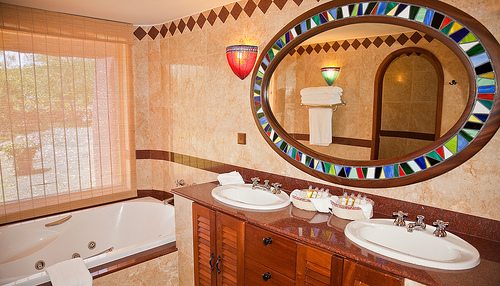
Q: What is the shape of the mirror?
A: Oval.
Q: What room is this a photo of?
A: Bathroom.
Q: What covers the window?
A: Blinds.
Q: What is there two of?
A: Sinks.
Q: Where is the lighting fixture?
A: On the wall.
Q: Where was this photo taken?
A: In the bathroom.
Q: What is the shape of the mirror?
A: Oval.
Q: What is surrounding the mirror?
A: Colorful tile.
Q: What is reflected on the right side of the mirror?
A: Doorway.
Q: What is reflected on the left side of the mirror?
A: Towels.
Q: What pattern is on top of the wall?
A: Diamonds.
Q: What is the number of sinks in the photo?
A: Two.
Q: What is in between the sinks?
A: Baskets.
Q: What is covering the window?
A: Blinds.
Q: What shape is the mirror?
A: Oval shaped.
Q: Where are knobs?
A: On drawers.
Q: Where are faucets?
A: Over the sinks.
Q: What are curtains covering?
A: A window.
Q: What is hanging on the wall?
A: A mirror.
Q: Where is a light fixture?
A: On the wall.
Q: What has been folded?
A: Towels.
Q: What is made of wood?
A: Drawers.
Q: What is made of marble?
A: The walls.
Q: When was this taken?
A: During the day.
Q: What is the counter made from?
A: Wood.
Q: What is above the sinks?
A: A large mirror.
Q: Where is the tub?
A: Underneath the window.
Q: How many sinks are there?
A: Two.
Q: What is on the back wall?
A: A shelf with towels.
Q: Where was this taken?
A: In a bathroom.